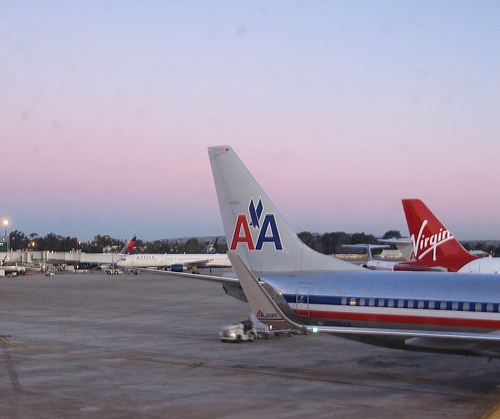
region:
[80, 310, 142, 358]
the ground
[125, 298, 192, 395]
the ground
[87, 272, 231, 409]
the ground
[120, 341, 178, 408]
the ground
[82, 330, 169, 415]
the ground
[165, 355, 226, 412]
the ground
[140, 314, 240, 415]
the ground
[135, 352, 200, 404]
the ground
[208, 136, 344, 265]
Tail of the plane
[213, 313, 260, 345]
A man driving the tram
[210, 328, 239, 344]
headlights of the cart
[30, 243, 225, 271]
Planes parked in the background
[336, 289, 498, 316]
Windows of the plane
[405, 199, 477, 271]
The red tail of a virgin plane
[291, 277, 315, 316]
The door on a plane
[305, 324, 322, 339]
A green light on the plane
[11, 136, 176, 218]
The sky at dawn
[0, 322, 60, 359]
Yellow marking on the runway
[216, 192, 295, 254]
the letters are red and blue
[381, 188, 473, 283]
the tail is red and white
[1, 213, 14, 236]
the pole light is on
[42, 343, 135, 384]
the tar mac is grey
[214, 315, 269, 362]
the baggage vehicle is white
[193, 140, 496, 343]
the plane is silver red and blue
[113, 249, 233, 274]
this plane is white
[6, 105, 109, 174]
part of the sky is pinkish purple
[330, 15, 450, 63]
this part of the sky looks hazy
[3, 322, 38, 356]
the line is yellow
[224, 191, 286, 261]
the AA logo on the tail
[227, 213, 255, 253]
the red A on the tail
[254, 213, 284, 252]
the blue A on the tail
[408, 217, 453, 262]
the white word Virgin on the tail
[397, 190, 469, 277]
the red tail on the plane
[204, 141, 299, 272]
the tail of the plane with AA on it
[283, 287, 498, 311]
the blue stripe on the plane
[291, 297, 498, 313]
the windows on the plane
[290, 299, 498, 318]
the white line on the plane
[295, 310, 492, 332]
the red line on the plane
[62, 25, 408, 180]
Sky is blue and pink color.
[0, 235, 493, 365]
Planes are standing in ground.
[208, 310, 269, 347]
Truck is besides the plane.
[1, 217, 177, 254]
Lights are on.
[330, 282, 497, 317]
Windows are attached to the sides of the plane.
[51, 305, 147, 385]
Ground is grey color.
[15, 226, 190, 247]
Trees are behind the plane.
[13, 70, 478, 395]
Picture is taken in airport.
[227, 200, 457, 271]
Company name is written in wings.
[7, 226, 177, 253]
Trees are green color.